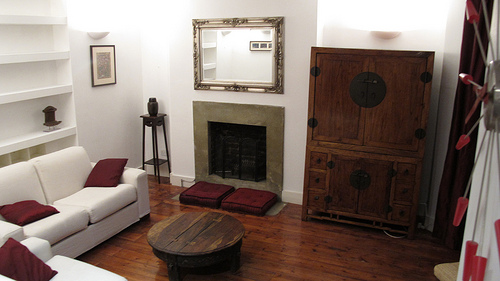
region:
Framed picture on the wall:
[86, 45, 118, 86]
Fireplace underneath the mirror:
[192, 115, 282, 190]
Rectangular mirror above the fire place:
[187, 13, 284, 96]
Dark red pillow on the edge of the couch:
[83, 156, 128, 188]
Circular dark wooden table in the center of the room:
[140, 203, 250, 265]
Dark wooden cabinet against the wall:
[286, 49, 436, 230]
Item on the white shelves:
[37, 105, 69, 132]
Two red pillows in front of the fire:
[175, 171, 276, 219]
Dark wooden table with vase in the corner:
[135, 89, 180, 177]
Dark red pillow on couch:
[1, 188, 63, 234]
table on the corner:
[137, 110, 169, 185]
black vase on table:
[145, 95, 158, 115]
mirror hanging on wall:
[191, 15, 283, 95]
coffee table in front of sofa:
[145, 208, 245, 278]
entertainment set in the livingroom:
[302, 45, 437, 237]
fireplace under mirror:
[190, 97, 283, 192]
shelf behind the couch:
[0, 5, 76, 166]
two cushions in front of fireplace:
[177, 177, 278, 212]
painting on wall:
[88, 41, 118, 86]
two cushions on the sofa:
[0, 156, 131, 226]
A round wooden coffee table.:
[143, 202, 248, 271]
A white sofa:
[2, 143, 157, 260]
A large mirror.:
[189, 15, 287, 97]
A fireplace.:
[190, 101, 280, 191]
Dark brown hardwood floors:
[75, 152, 462, 279]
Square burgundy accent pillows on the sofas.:
[0, 152, 127, 279]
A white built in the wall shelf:
[0, 4, 83, 170]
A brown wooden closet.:
[300, 44, 435, 240]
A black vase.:
[144, 94, 159, 115]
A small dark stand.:
[140, 112, 174, 182]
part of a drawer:
[389, 180, 399, 195]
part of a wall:
[302, 117, 304, 122]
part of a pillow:
[114, 176, 122, 182]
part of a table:
[214, 243, 225, 253]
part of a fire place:
[226, 132, 235, 153]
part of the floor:
[271, 232, 278, 241]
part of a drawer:
[338, 163, 345, 177]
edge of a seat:
[101, 198, 115, 223]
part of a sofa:
[53, 210, 66, 225]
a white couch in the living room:
[0, 143, 151, 279]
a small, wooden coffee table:
[147, 209, 245, 271]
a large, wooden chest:
[300, 45, 436, 238]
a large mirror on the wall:
[190, 14, 285, 94]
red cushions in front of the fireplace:
[179, 178, 276, 216]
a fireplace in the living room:
[191, 98, 285, 200]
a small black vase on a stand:
[147, 96, 159, 117]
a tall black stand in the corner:
[139, 112, 171, 184]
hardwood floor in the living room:
[73, 168, 460, 279]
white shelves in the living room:
[0, 0, 80, 172]